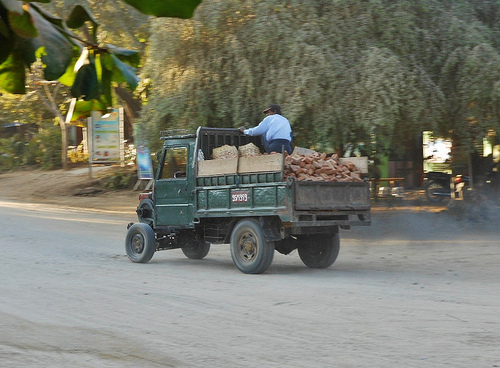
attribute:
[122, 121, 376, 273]
truck — green, numbered, full, lettered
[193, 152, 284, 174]
board — brown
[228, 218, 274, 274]
wheel — black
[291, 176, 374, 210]
gate — black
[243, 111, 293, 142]
shirt — blue, long sleeve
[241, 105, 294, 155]
man — wearing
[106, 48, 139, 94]
leaf — green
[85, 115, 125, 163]
sign — written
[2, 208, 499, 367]
road — dirt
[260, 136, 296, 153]
pants — dark